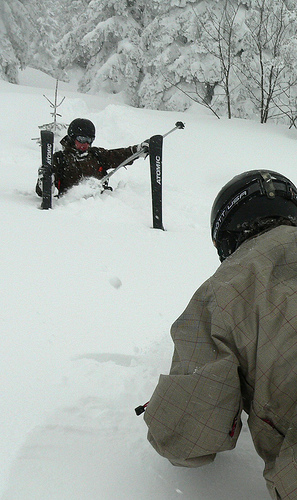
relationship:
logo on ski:
[155, 155, 162, 185] [128, 133, 170, 246]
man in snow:
[35, 118, 151, 200] [1, 203, 152, 347]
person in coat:
[134, 168, 296, 498] [146, 232, 295, 496]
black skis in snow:
[149, 134, 167, 231] [39, 232, 128, 314]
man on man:
[35, 118, 151, 200] [35, 118, 151, 200]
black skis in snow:
[149, 134, 167, 231] [16, 242, 109, 332]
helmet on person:
[207, 168, 295, 241] [135, 167, 291, 443]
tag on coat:
[131, 403, 146, 417] [143, 224, 297, 499]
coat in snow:
[143, 224, 297, 499] [2, 117, 294, 494]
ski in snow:
[40, 129, 54, 209] [54, 192, 177, 304]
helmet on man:
[64, 116, 102, 151] [35, 118, 151, 200]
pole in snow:
[90, 114, 197, 202] [52, 188, 190, 311]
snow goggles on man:
[68, 133, 98, 145] [35, 118, 151, 200]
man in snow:
[35, 118, 151, 200] [0, 86, 295, 377]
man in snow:
[36, 116, 149, 201] [1, 80, 294, 498]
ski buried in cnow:
[40, 129, 54, 209] [31, 200, 70, 244]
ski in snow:
[40, 129, 52, 208] [1, 80, 294, 498]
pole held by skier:
[100, 121, 185, 187] [36, 113, 183, 227]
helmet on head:
[209, 168, 297, 241] [212, 175, 295, 269]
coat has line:
[143, 224, 297, 499] [227, 274, 242, 295]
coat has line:
[143, 224, 297, 499] [237, 307, 253, 324]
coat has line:
[143, 224, 297, 499] [195, 299, 209, 322]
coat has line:
[143, 224, 297, 499] [190, 393, 214, 405]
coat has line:
[143, 224, 297, 499] [163, 399, 183, 413]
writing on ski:
[46, 141, 52, 165] [40, 129, 54, 209]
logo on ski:
[156, 155, 161, 186] [147, 133, 166, 231]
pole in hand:
[100, 121, 185, 187] [131, 136, 156, 166]